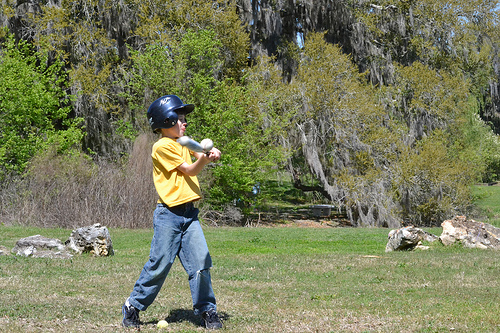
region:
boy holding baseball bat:
[108, 75, 223, 206]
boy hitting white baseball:
[134, 99, 246, 220]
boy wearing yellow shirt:
[128, 94, 244, 251]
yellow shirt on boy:
[148, 107, 210, 227]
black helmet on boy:
[143, 87, 243, 191]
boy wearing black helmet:
[129, 80, 220, 210]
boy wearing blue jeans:
[146, 109, 245, 322]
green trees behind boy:
[8, 34, 105, 216]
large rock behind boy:
[10, 232, 158, 299]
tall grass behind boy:
[20, 103, 176, 222]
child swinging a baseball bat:
[109, 87, 231, 331]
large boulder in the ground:
[62, 220, 114, 262]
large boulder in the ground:
[7, 228, 73, 263]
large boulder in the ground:
[381, 223, 446, 255]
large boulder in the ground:
[435, 208, 499, 260]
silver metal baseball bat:
[175, 135, 228, 156]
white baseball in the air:
[199, 136, 219, 153]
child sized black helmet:
[136, 83, 201, 134]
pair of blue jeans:
[125, 192, 221, 307]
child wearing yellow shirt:
[95, 85, 264, 327]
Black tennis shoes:
[118, 299, 227, 330]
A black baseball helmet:
[136, 92, 198, 126]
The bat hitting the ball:
[177, 130, 227, 159]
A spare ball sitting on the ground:
[150, 312, 175, 331]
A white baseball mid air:
[197, 130, 209, 147]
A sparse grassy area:
[245, 235, 366, 325]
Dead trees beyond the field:
[17, 144, 149, 225]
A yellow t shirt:
[145, 141, 200, 204]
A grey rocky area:
[385, 213, 495, 261]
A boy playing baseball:
[129, 89, 231, 321]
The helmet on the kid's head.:
[144, 92, 191, 123]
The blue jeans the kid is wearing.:
[139, 198, 215, 303]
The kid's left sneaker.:
[119, 293, 149, 331]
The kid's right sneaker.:
[196, 307, 224, 327]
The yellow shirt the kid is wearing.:
[151, 141, 201, 201]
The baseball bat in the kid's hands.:
[181, 138, 213, 155]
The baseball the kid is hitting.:
[197, 135, 218, 149]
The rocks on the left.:
[10, 210, 106, 265]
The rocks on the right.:
[378, 196, 494, 272]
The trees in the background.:
[3, 2, 498, 229]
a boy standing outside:
[73, 13, 270, 330]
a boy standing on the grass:
[59, 16, 301, 331]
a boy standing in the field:
[19, 41, 284, 332]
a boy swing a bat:
[57, 32, 287, 332]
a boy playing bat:
[100, 56, 282, 326]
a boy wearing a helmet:
[79, 27, 271, 329]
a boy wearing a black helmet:
[93, 57, 295, 327]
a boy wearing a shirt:
[99, 57, 288, 324]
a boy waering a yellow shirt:
[109, 58, 282, 330]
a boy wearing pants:
[68, 28, 287, 330]